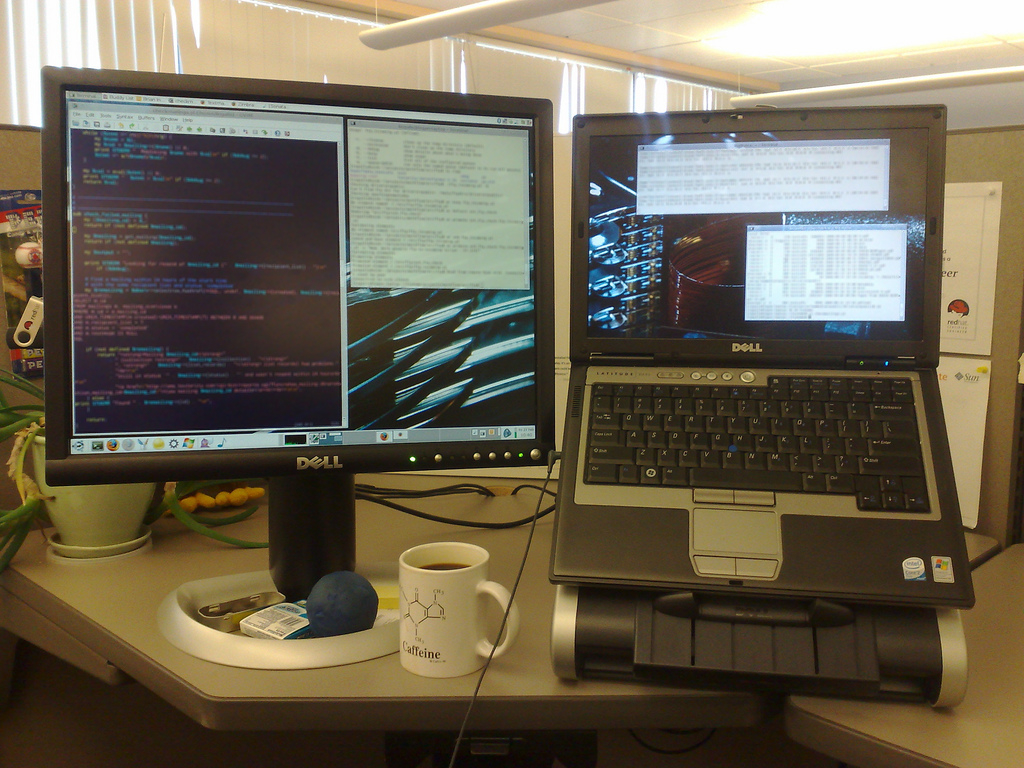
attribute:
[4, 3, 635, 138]
curtain — white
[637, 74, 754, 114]
curtain — white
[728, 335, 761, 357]
letters — gray, dell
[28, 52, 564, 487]
monitor — flat-screen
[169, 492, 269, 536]
leaf — green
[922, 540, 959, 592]
sticker — silver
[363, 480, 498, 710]
cup — white 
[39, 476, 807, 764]
desk — gray 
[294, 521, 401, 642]
ball — round , blue 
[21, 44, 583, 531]
screen — black 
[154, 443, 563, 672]
desk — grey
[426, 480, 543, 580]
wires — black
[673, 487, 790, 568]
mouse pad — grey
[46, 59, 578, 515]
computer monitor — black, dell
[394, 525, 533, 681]
mug — white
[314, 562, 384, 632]
ball — blue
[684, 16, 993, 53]
light — glowing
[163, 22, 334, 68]
blinds — vertical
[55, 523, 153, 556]
base — round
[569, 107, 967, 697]
laptop — open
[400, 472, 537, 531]
wires — black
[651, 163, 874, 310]
image — glowing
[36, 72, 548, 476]
computer monitor — black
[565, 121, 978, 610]
laptop — black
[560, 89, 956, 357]
lid — open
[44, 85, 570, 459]
monitor — on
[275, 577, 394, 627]
stress ball — blue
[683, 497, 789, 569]
track pad — gray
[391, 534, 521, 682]
cup — white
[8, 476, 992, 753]
desk — gray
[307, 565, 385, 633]
ball — blue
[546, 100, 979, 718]
laptop — black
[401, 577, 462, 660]
design — black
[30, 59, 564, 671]
monitor — black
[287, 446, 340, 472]
letters — gray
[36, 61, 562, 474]
screen — black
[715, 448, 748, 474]
key — black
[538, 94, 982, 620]
laptop — black